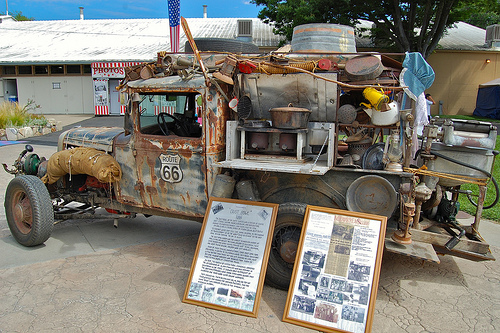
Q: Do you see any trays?
A: No, there are no trays.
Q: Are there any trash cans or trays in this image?
A: No, there are no trays or trash cans.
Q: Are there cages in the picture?
A: No, there are no cages.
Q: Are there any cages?
A: No, there are no cages.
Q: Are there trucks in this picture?
A: Yes, there is a truck.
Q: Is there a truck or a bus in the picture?
A: Yes, there is a truck.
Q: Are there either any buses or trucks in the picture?
A: Yes, there is a truck.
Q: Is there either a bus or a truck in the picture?
A: Yes, there is a truck.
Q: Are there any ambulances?
A: No, there are no ambulances.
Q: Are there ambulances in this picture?
A: No, there are no ambulances.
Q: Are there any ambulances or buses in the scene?
A: No, there are no ambulances or buses.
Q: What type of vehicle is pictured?
A: The vehicle is a truck.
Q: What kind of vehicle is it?
A: The vehicle is a truck.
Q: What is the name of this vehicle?
A: This is a truck.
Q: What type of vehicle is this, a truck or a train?
A: This is a truck.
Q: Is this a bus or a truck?
A: This is a truck.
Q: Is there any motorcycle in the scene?
A: No, there are no motorcycles.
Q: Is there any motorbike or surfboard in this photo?
A: No, there are no motorcycles or surfboards.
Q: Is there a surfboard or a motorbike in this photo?
A: No, there are no motorcycles or surfboards.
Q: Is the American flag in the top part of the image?
A: Yes, the American flag is in the top of the image.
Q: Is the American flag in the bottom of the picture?
A: No, the American flag is in the top of the image.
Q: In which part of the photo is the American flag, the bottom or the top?
A: The American flag is in the top of the image.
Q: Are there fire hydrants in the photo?
A: No, there are no fire hydrants.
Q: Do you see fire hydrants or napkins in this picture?
A: No, there are no fire hydrants or napkins.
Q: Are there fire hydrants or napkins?
A: No, there are no fire hydrants or napkins.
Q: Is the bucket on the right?
A: Yes, the bucket is on the right of the image.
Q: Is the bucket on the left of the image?
A: No, the bucket is on the right of the image.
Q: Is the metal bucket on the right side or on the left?
A: The bucket is on the right of the image.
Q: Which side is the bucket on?
A: The bucket is on the right of the image.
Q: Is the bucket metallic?
A: Yes, the bucket is metallic.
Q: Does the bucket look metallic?
A: Yes, the bucket is metallic.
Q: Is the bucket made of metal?
A: Yes, the bucket is made of metal.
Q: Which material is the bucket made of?
A: The bucket is made of metal.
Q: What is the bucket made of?
A: The bucket is made of metal.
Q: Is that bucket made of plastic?
A: No, the bucket is made of metal.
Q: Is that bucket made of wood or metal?
A: The bucket is made of metal.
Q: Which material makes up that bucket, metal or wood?
A: The bucket is made of metal.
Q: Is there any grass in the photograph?
A: Yes, there is grass.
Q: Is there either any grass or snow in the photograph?
A: Yes, there is grass.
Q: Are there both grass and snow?
A: No, there is grass but no snow.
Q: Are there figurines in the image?
A: No, there are no figurines.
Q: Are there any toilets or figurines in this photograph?
A: No, there are no figurines or toilets.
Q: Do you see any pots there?
A: Yes, there is a pot.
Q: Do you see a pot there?
A: Yes, there is a pot.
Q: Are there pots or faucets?
A: Yes, there is a pot.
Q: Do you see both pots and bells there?
A: No, there is a pot but no bells.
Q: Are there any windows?
A: Yes, there is a window.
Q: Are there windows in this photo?
A: Yes, there is a window.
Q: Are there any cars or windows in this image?
A: Yes, there is a window.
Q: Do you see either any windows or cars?
A: Yes, there is a window.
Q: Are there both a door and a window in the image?
A: Yes, there are both a window and a door.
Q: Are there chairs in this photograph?
A: No, there are no chairs.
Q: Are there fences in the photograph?
A: No, there are no fences.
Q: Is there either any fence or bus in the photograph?
A: No, there are no fences or buses.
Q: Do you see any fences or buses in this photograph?
A: No, there are no fences or buses.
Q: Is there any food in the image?
A: No, there is no food.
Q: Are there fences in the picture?
A: No, there are no fences.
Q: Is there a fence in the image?
A: No, there are no fences.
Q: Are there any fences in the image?
A: No, there are no fences.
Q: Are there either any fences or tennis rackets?
A: No, there are no fences or tennis rackets.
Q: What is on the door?
A: The logo is on the door.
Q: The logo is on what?
A: The logo is on the door.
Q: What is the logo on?
A: The logo is on the door.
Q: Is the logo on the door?
A: Yes, the logo is on the door.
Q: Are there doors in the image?
A: Yes, there is a door.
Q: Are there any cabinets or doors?
A: Yes, there is a door.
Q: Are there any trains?
A: No, there are no trains.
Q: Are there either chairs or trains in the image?
A: No, there are no trains or chairs.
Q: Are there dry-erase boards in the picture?
A: No, there are no dry-erase boards.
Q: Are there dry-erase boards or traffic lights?
A: No, there are no dry-erase boards or traffic lights.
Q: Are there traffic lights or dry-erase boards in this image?
A: No, there are no dry-erase boards or traffic lights.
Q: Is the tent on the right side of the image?
A: Yes, the tent is on the right of the image.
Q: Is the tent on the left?
A: No, the tent is on the right of the image.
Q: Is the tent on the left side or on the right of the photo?
A: The tent is on the right of the image.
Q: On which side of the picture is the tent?
A: The tent is on the right of the image.